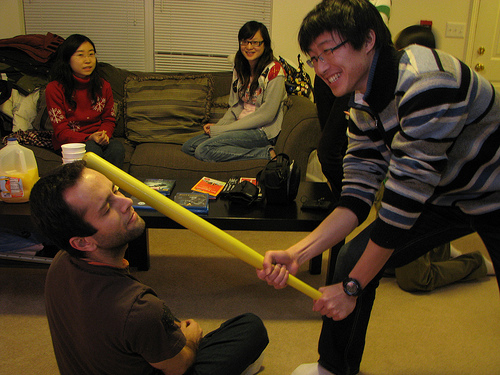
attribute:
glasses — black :
[304, 36, 359, 65]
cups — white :
[61, 143, 89, 163]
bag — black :
[254, 150, 299, 206]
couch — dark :
[1, 29, 323, 180]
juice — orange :
[0, 138, 40, 202]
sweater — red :
[56, 82, 103, 125]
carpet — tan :
[373, 296, 497, 374]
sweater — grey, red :
[41, 54, 134, 146]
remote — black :
[219, 171, 247, 203]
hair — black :
[55, 27, 115, 108]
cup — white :
[62, 142, 84, 152]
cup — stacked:
[59, 143, 86, 151]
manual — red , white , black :
[189, 175, 226, 198]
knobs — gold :
[466, 40, 490, 87]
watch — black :
[338, 277, 367, 299]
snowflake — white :
[46, 105, 66, 126]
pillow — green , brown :
[119, 70, 214, 147]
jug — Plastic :
[3, 125, 51, 226]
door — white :
[458, 10, 499, 84]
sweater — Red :
[58, 77, 142, 134]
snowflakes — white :
[42, 82, 117, 139]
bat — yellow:
[82, 152, 322, 300]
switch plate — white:
[439, 18, 469, 42]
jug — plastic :
[0, 137, 40, 202]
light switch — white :
[443, 19, 470, 39]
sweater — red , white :
[42, 77, 119, 152]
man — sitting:
[27, 157, 270, 372]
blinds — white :
[33, 8, 264, 75]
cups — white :
[60, 139, 88, 172]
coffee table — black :
[0, 179, 332, 274]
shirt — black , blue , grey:
[318, 27, 493, 250]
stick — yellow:
[78, 140, 339, 306]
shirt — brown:
[37, 236, 187, 371]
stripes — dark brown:
[123, 78, 208, 142]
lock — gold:
[469, 40, 483, 71]